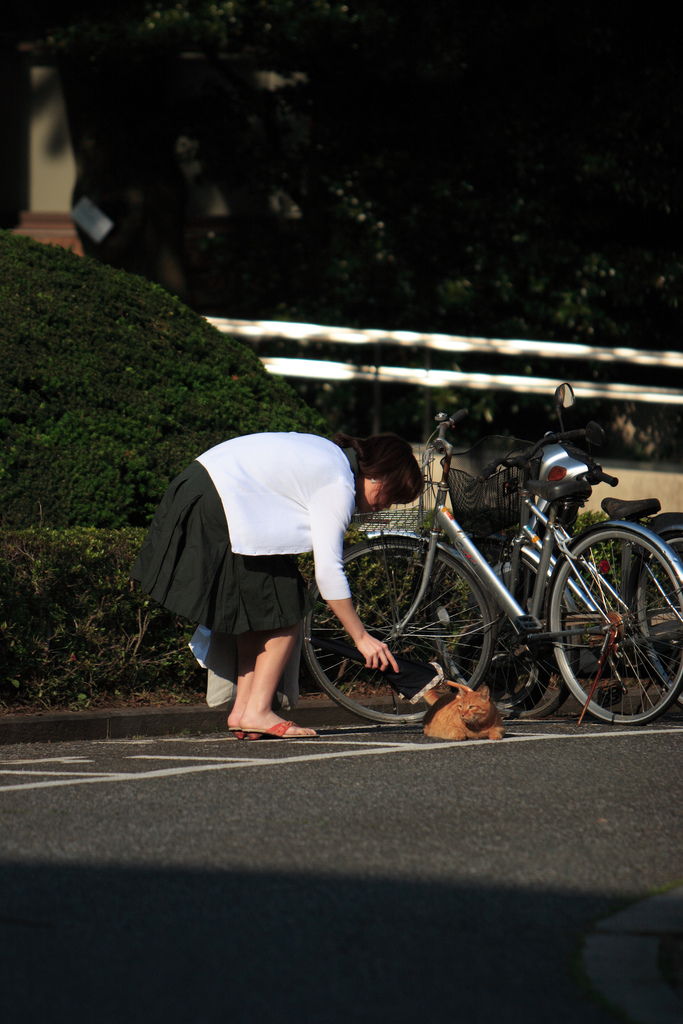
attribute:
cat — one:
[420, 680, 508, 743]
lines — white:
[2, 730, 644, 818]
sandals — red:
[227, 696, 316, 755]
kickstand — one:
[568, 635, 608, 733]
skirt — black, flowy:
[133, 473, 315, 646]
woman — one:
[148, 424, 414, 733]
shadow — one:
[20, 819, 662, 997]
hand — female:
[349, 640, 397, 673]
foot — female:
[241, 715, 315, 751]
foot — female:
[219, 707, 241, 731]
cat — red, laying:
[412, 680, 521, 750]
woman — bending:
[123, 421, 443, 761]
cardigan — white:
[181, 424, 368, 618]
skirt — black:
[109, 449, 327, 657]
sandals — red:
[226, 718, 315, 746]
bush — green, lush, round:
[1, 208, 390, 540]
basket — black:
[438, 455, 544, 549]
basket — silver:
[350, 466, 460, 560]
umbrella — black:
[290, 604, 489, 741]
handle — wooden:
[423, 662, 490, 702]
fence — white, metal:
[167, 286, 678, 485]